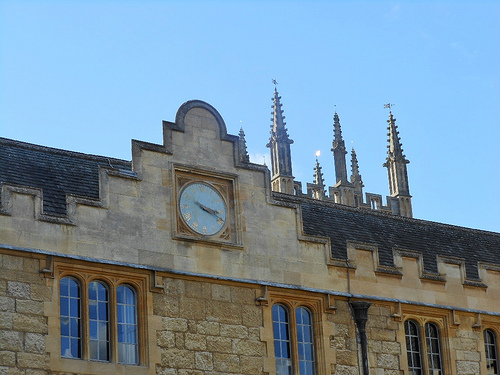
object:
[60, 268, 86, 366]
window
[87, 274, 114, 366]
window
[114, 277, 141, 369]
window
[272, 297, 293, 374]
window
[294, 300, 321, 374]
window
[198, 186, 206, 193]
number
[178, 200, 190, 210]
number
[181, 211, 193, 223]
number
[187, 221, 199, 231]
number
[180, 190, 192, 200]
number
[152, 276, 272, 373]
stones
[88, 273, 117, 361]
window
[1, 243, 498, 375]
wall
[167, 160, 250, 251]
clock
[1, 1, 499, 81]
sky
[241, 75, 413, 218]
building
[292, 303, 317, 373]
window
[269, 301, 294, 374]
window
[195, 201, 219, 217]
hand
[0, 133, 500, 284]
roof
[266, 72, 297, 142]
spire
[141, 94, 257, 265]
clock building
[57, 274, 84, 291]
arch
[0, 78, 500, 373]
building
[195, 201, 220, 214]
hands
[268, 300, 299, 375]
window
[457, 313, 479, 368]
stone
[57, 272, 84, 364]
window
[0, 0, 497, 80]
blue sky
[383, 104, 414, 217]
steeple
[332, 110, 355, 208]
steeple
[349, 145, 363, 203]
steeple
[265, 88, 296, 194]
steeple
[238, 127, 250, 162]
steeple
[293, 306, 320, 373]
narrow window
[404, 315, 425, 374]
window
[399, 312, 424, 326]
arch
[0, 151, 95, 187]
bricks